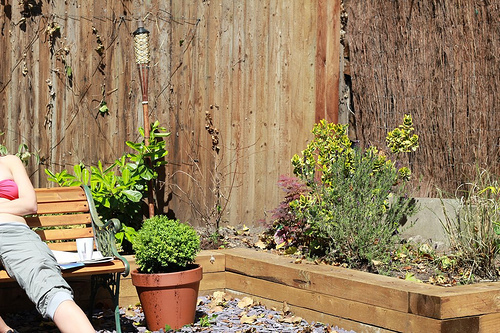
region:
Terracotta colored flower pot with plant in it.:
[127, 263, 202, 330]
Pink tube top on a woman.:
[0, 178, 20, 202]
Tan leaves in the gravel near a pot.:
[210, 290, 252, 317]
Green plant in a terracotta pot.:
[132, 214, 200, 269]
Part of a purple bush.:
[266, 168, 318, 245]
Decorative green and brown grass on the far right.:
[427, 163, 499, 287]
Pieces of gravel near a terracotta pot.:
[216, 314, 237, 331]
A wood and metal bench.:
[1, 183, 128, 332]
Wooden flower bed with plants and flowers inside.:
[0, 249, 499, 332]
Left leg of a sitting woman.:
[2, 231, 105, 332]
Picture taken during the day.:
[15, 15, 483, 301]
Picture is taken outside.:
[22, 12, 474, 176]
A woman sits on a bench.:
[7, 140, 96, 331]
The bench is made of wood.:
[54, 189, 74, 223]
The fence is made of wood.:
[179, 15, 304, 189]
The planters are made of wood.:
[216, 245, 461, 332]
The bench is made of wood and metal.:
[47, 187, 103, 256]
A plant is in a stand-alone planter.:
[122, 218, 212, 331]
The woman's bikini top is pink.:
[0, 164, 18, 204]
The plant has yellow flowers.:
[278, 111, 422, 196]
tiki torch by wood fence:
[120, 21, 172, 184]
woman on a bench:
[1, 85, 147, 330]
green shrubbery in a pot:
[127, 173, 204, 330]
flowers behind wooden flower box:
[235, 93, 463, 310]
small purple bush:
[260, 161, 319, 243]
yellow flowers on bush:
[302, 121, 383, 201]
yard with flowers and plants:
[97, 39, 450, 325]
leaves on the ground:
[211, 291, 273, 331]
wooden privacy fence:
[42, 0, 273, 219]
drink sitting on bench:
[55, 211, 123, 326]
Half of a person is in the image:
[0, 128, 107, 332]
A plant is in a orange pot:
[123, 206, 211, 332]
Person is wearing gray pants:
[2, 222, 79, 313]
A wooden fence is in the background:
[5, 0, 335, 175]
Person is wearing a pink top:
[3, 173, 26, 199]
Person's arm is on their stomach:
[2, 155, 42, 220]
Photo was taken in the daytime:
[4, 55, 471, 330]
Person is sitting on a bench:
[1, 142, 129, 330]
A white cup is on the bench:
[58, 230, 111, 276]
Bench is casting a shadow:
[16, 303, 136, 330]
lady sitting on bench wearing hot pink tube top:
[1, 133, 92, 332]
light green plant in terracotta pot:
[128, 210, 210, 332]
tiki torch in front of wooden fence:
[123, 11, 166, 136]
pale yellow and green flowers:
[280, 103, 432, 272]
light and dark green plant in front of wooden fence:
[80, 141, 172, 206]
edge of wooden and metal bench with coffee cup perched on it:
[53, 186, 128, 291]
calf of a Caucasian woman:
[30, 283, 96, 332]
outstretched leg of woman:
[3, 221, 97, 331]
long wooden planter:
[222, 233, 499, 332]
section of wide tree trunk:
[338, 4, 499, 134]